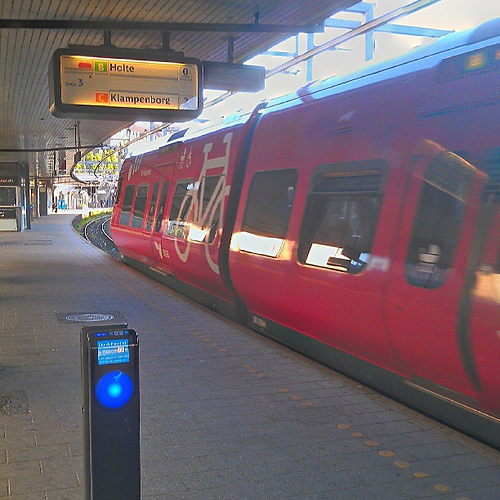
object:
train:
[108, 14, 499, 451]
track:
[100, 217, 115, 243]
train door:
[152, 178, 173, 270]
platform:
[0, 207, 499, 499]